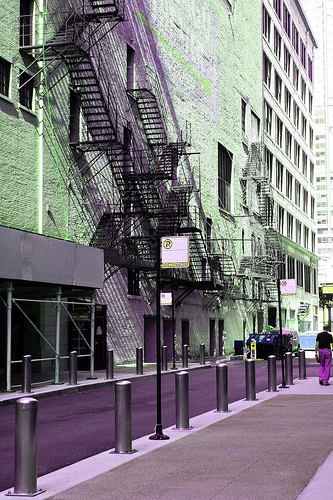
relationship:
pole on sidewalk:
[147, 234, 169, 442] [33, 369, 332, 498]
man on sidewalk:
[307, 317, 331, 384] [7, 361, 331, 498]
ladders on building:
[27, 14, 232, 310] [0, 0, 316, 371]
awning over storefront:
[20, 219, 123, 292] [3, 7, 270, 387]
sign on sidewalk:
[159, 235, 190, 272] [107, 413, 331, 499]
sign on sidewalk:
[159, 235, 190, 272] [36, 338, 331, 500]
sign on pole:
[160, 235, 189, 265] [147, 234, 169, 442]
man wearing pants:
[312, 321, 332, 386] [317, 348, 330, 383]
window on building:
[283, 83, 292, 116] [0, 0, 316, 371]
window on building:
[302, 149, 307, 176] [0, 0, 316, 371]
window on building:
[292, 20, 298, 53] [0, 0, 316, 371]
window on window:
[261, 1, 270, 42] [308, 55, 311, 82]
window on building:
[308, 55, 311, 82] [0, 0, 316, 371]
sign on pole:
[159, 235, 190, 272] [149, 236, 168, 439]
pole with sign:
[147, 228, 169, 441] [156, 230, 192, 270]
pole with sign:
[147, 234, 169, 442] [159, 230, 195, 269]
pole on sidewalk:
[147, 234, 169, 442] [69, 402, 309, 493]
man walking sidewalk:
[312, 321, 332, 386] [89, 374, 320, 498]